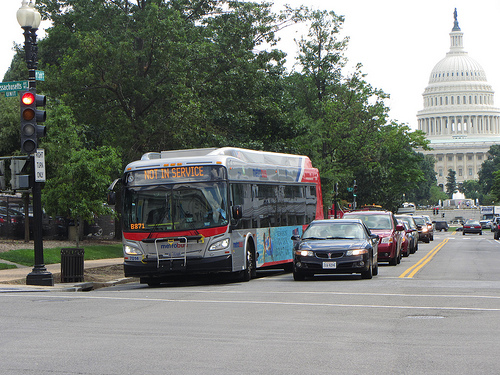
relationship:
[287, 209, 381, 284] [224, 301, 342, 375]
car on street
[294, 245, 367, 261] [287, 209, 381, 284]
headlight on vehicle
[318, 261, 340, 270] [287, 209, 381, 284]
license plate vehicle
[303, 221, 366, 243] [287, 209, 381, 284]
window on vehicle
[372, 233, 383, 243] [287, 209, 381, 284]
side mirror vehicle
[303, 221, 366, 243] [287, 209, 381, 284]
windshield wiper vehicle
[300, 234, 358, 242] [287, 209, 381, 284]
wiper on vehicle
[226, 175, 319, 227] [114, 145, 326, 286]
windows on bus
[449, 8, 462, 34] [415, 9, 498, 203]
statue top building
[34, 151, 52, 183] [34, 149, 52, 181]
black white sign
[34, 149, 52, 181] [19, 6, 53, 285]
sign on pole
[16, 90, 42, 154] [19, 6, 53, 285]
signal on pole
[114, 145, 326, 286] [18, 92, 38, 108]
bus red light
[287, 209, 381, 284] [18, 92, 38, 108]
car red light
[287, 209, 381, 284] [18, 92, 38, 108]
car stopped light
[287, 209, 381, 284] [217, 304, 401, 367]
car driving road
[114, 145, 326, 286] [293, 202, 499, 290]
bus in traffic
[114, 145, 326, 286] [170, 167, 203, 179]
bus not service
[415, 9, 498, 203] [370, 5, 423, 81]
monument in background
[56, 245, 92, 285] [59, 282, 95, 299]
garbage can corner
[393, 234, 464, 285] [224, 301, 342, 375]
lines in street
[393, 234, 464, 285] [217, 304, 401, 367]
lines on road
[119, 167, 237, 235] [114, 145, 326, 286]
windshield on bus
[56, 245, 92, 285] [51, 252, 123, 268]
trash can sidewalk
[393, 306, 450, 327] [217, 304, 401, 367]
manhole on road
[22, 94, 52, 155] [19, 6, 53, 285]
lights on pole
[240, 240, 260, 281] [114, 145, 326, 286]
tire on bus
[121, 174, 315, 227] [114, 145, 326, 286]
window on bus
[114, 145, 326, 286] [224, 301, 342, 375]
bus on street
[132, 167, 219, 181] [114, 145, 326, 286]
words on bus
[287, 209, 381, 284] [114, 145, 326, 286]
car next bus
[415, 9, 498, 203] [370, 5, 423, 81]
building in background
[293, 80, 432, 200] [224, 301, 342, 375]
trees line street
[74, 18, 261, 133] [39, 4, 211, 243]
leaves on tree